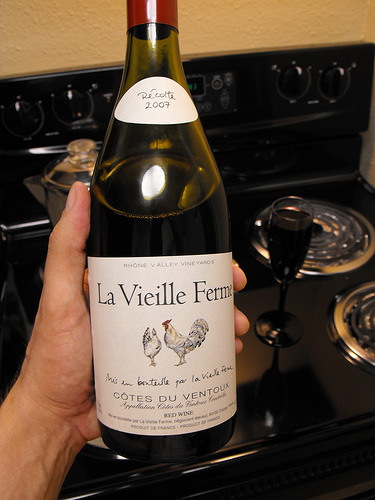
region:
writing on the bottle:
[82, 280, 241, 314]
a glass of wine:
[270, 200, 312, 283]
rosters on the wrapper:
[133, 313, 214, 368]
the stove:
[285, 367, 355, 416]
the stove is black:
[276, 376, 337, 414]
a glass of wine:
[237, 198, 309, 340]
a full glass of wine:
[268, 170, 300, 330]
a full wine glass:
[262, 196, 323, 365]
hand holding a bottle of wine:
[54, 191, 244, 493]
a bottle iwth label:
[75, 228, 243, 472]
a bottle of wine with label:
[88, 250, 253, 427]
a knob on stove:
[314, 62, 350, 111]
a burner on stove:
[286, 196, 362, 268]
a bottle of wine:
[68, 114, 290, 448]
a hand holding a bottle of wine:
[54, 161, 325, 477]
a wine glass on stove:
[255, 199, 305, 322]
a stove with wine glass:
[251, 196, 305, 349]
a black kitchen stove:
[249, 193, 374, 454]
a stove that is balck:
[234, 185, 370, 413]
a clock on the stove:
[186, 63, 206, 101]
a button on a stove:
[204, 74, 224, 90]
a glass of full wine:
[241, 182, 319, 325]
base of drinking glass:
[257, 303, 309, 350]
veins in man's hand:
[28, 419, 83, 479]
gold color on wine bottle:
[98, 131, 214, 196]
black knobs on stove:
[279, 54, 356, 107]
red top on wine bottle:
[118, 5, 201, 41]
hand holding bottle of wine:
[92, 0, 252, 462]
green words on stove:
[189, 71, 209, 94]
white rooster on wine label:
[160, 312, 211, 368]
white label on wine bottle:
[84, 243, 240, 446]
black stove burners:
[245, 195, 373, 381]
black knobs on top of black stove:
[265, 56, 359, 109]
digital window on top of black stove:
[185, 75, 206, 96]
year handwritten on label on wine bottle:
[142, 100, 172, 112]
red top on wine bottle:
[124, 0, 183, 38]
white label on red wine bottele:
[84, 247, 243, 427]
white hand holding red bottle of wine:
[0, 0, 248, 495]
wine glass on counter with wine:
[252, 188, 312, 348]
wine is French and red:
[82, 249, 262, 444]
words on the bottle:
[61, 249, 256, 335]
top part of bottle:
[89, 15, 225, 98]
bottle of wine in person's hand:
[84, 0, 244, 468]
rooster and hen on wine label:
[135, 317, 212, 369]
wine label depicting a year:
[109, 74, 203, 127]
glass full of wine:
[255, 193, 317, 350]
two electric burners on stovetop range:
[247, 195, 373, 370]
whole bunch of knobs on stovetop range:
[3, 57, 365, 141]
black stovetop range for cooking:
[0, 38, 373, 499]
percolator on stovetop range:
[20, 137, 100, 248]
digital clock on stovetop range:
[179, 74, 209, 97]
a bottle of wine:
[74, 8, 247, 461]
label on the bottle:
[85, 247, 246, 443]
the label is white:
[75, 247, 252, 434]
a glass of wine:
[252, 189, 328, 370]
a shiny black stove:
[18, 47, 367, 486]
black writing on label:
[93, 275, 237, 313]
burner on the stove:
[235, 182, 368, 288]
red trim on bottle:
[117, 2, 195, 52]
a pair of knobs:
[268, 56, 357, 111]